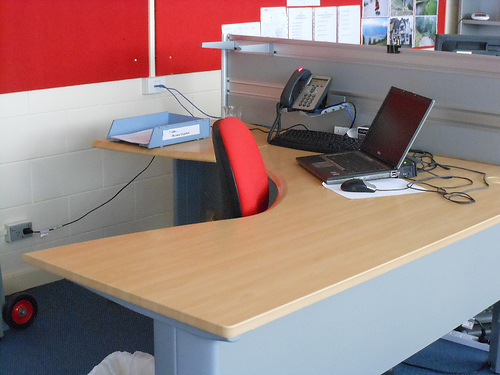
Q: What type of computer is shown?
A: A laptop.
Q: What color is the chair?
A: Orange.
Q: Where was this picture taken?
A: An office.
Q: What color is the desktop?
A: Oak.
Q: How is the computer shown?
A: Open.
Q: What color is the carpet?
A: Blue.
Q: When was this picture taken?
A: Daytime.